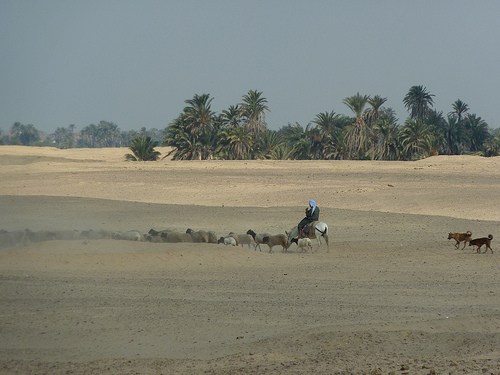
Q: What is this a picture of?
A: A desert.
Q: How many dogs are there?
A: Two.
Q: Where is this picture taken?
A: A desert.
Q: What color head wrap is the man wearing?
A: Blue.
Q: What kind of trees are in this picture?
A: Palm trees.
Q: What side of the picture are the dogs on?
A: Right.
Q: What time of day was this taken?
A: Day time.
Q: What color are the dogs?
A: Brown.